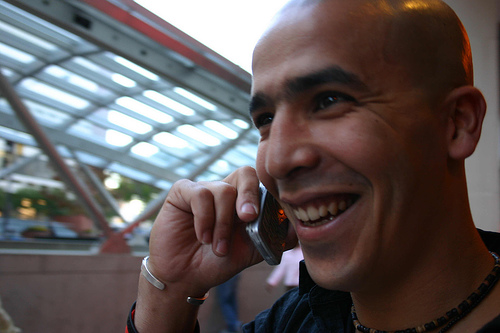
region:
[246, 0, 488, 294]
A head that has been shaved and polished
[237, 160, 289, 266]
Silver phone with a finger on the side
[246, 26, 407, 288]
A smiling face with laugh lines around the eye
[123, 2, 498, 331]
Man talking on a phone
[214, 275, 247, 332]
Legs of a person behind the man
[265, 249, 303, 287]
Person's light pink jacket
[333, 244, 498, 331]
Brown bead necklace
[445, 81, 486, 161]
A person's ear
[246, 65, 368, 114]
A pair of heavy, dark eyebrows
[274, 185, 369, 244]
Smiling mouth with teeth showing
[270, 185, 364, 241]
A man with a smile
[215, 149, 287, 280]
A man talking on a cell phone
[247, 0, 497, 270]
A man with a bald head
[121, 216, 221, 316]
Wrist with a silver bracelet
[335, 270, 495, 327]
Necklace around mans neck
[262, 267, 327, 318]
A dark colored shirt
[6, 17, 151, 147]
A metal cover with red trim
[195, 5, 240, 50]
A clear sky behind man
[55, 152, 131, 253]
A metal pole behind man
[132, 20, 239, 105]
Red trim on metal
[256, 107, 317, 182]
a nose on a bald man's face.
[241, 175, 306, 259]
A phone against a man's face.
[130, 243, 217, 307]
a wrist watch.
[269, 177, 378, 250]
a man's smile with teeth showing.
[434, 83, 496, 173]
an ear on a bald man.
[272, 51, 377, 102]
an eye brown on a man.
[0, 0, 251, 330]
A covering near a man.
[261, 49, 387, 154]
a left eye on a man.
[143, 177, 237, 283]
fingers on a man's hand.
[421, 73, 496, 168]
a left man's shiney ear.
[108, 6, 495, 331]
A happy stranger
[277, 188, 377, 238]
A big smile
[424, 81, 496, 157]
A left ear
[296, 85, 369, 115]
The left eye of a mans face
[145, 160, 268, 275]
Right hand holding a phone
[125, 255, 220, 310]
A silver wrist watch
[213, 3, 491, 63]
A very cerebral head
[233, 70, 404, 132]
Two eyes looking straight ahead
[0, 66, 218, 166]
A very blurry background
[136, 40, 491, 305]
A man making plans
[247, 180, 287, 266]
a silver cell phone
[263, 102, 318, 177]
the nose of the man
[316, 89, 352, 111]
the eye of the man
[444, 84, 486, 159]
the ear of the man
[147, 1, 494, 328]
a man wearing a necklace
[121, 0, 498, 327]
a man wearing a bracelet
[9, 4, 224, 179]
windows behind the man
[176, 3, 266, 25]
a clear sky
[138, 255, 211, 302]
the bracelet on the arm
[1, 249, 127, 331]
a concrete wall